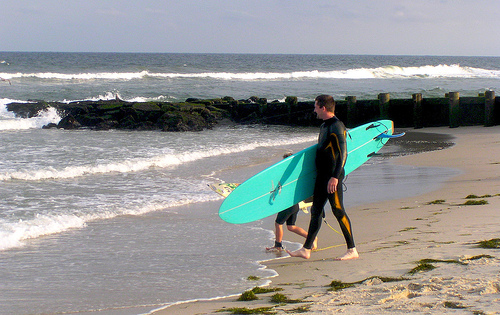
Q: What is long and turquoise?
A: Surfboard.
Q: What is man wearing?
A: Wetsuit.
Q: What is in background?
A: Waves.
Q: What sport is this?
A: Surfing.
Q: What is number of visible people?
A: Two.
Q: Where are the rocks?
A: In the ocean.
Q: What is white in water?
A: Waves.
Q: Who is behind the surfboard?
A: A little boy.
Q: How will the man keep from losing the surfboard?
A: Tether.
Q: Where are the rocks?
A: Close to the shore.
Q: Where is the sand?
A: On the beach.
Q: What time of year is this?
A: Summer.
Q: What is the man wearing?
A: Wetsuit.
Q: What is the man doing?
A: Carrying surfboard.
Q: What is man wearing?
A: Wetsuit.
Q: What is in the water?
A: Breaker wall.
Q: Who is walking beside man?
A: Little boy.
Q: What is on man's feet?
A: Nothing.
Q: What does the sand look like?
A: Wet.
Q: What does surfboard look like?
A: Blue.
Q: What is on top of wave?
A: White cap.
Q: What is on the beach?
A: Tracks.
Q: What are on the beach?
A: Tracks.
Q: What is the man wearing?
A: Suit.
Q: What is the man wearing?
A: Suit.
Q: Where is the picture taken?
A: Beach.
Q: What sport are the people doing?
A: Surfing.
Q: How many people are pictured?
A: Two.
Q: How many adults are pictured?
A: One.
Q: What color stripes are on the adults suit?
A: Yellow.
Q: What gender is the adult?
A: Male.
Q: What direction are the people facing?
A: Left.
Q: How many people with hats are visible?
A: None.